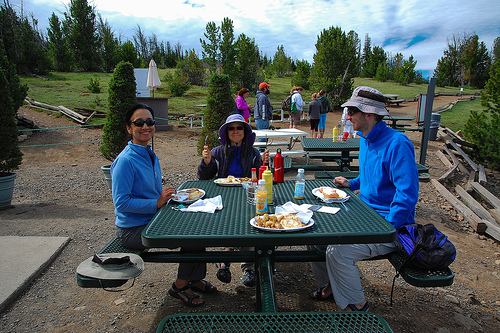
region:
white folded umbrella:
[142, 54, 164, 96]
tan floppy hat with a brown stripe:
[340, 82, 390, 118]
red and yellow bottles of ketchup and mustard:
[257, 159, 276, 204]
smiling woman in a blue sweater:
[110, 101, 178, 248]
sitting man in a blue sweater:
[331, 79, 423, 306]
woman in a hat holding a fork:
[192, 109, 269, 177]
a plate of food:
[247, 208, 317, 233]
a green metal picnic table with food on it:
[147, 171, 403, 331]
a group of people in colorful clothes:
[232, 78, 332, 138]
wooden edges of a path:
[433, 89, 498, 239]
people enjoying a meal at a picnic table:
[116, 88, 423, 266]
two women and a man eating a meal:
[110, 98, 406, 249]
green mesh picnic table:
[172, 175, 383, 318]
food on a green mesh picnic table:
[177, 175, 351, 233]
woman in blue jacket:
[106, 101, 181, 251]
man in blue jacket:
[334, 88, 437, 258]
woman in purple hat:
[201, 111, 269, 165]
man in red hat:
[251, 77, 281, 129]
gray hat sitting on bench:
[61, 238, 175, 297]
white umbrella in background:
[138, 57, 178, 104]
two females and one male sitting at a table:
[95, 96, 464, 292]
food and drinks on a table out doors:
[158, 162, 359, 232]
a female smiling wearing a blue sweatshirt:
[99, 107, 194, 238]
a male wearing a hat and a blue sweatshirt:
[331, 77, 438, 238]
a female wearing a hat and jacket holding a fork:
[186, 109, 288, 185]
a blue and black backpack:
[387, 215, 458, 285]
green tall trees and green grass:
[212, 2, 491, 105]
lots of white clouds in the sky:
[83, 5, 498, 67]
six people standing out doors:
[215, 72, 370, 144]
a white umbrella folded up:
[134, 47, 213, 144]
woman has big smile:
[114, 94, 159, 158]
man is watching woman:
[339, 78, 412, 225]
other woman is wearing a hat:
[202, 106, 266, 174]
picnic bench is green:
[99, 171, 424, 331]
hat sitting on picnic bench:
[74, 241, 149, 288]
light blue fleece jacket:
[105, 136, 167, 228]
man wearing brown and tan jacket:
[344, 83, 395, 145]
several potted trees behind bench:
[14, 67, 237, 184]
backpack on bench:
[396, 211, 461, 279]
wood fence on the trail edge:
[427, 105, 495, 240]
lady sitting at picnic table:
[106, 91, 232, 309]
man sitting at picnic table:
[314, 67, 440, 324]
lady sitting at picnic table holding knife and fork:
[191, 100, 284, 230]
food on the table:
[173, 142, 373, 243]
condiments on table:
[237, 150, 323, 207]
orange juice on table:
[245, 175, 281, 223]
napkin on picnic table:
[174, 193, 246, 220]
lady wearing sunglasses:
[115, 99, 178, 159]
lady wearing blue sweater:
[102, 91, 198, 273]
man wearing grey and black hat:
[325, 66, 432, 160]